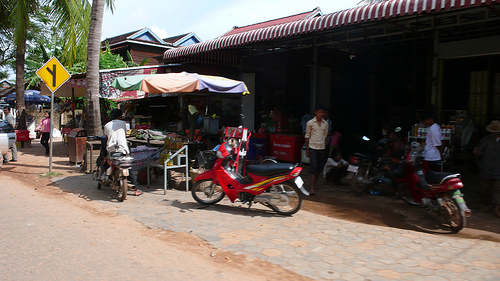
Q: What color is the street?
A: Gray.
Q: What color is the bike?
A: Red.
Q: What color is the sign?
A: Yellow.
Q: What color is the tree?
A: Brown.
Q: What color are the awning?
A: Red and white.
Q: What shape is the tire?
A: Round.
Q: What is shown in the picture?
A: A street.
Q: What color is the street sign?
A: Yellow.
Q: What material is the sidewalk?
A: Cobblestone.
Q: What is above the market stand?
A: A canopy.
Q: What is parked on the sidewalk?
A: Scooters.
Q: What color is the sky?
A: Blue.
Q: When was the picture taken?
A: Daytime.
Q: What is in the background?
A: Trees.